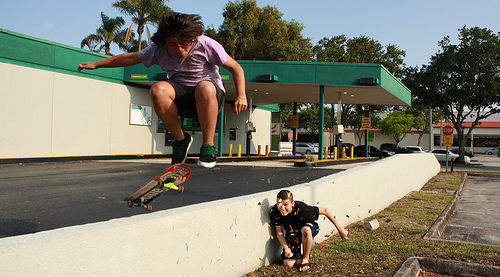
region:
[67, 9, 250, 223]
boy skating on a ramp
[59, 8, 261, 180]
boy has right hand extended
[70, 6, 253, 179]
man wears a purple tee shirt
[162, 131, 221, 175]
shoes are black with white soles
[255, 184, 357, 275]
a young boy hides behind a wall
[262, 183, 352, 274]
a boy wearing a black shirt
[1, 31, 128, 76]
roof of a building is green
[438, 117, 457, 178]
stop sign on a corner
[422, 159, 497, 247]
parking lot in front of a building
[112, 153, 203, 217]
skateboard is in the air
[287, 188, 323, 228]
black shirt of little kid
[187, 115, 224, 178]
black shoes of skater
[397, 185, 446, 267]
grass outside of building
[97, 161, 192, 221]
brown and red skateboard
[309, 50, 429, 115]
portion of bank building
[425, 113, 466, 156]
stop sign in back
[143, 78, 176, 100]
kneecap of skater in air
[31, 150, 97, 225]
asphalt of bank building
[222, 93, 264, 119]
left hand of skater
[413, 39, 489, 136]
big trees in back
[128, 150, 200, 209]
skateboard beneath guy's feet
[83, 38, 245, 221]
man in the air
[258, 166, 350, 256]
kid watching friend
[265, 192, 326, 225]
black shirt on kid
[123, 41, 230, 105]
purple shirt on kid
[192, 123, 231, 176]
black and white shoes with green laces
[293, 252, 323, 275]
kid wearing sandles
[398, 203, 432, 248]
green grass near people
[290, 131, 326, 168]
car in the background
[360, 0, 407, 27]
blue sky in background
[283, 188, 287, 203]
face of a boy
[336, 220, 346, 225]
arm of a boy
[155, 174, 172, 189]
part of a board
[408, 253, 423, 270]
edge of a pavement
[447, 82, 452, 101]
edge of a tree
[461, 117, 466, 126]
stem of a tree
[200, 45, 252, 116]
the arm of a boy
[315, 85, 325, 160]
a long green pole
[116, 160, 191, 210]
a red and white skateboard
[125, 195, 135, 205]
the wheel of a skateboard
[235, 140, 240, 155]
a small yellow pole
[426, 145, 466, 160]
a small white car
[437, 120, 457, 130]
a red and white stop sign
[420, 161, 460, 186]
a small section of green grass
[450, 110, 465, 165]
the branch of a tree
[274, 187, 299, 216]
the head of a boy